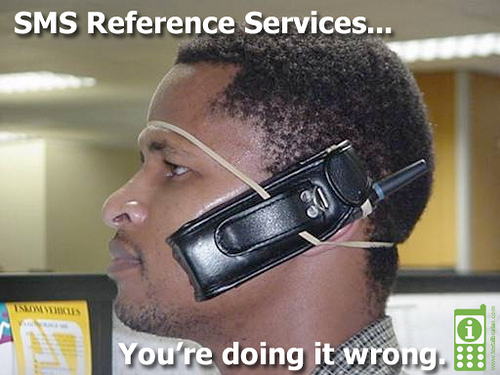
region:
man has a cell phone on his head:
[81, 8, 453, 368]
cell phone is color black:
[163, 128, 433, 318]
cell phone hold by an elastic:
[131, 105, 433, 305]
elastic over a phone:
[228, 162, 338, 267]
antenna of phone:
[376, 148, 436, 202]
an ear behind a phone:
[303, 208, 365, 265]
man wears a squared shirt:
[88, 8, 450, 373]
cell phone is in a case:
[162, 126, 437, 310]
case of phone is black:
[161, 135, 381, 312]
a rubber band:
[213, 149, 227, 169]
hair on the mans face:
[125, 308, 163, 329]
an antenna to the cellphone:
[380, 160, 430, 189]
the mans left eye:
[163, 160, 193, 177]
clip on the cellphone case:
[210, 213, 266, 257]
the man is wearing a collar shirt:
[361, 337, 391, 344]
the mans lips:
[102, 241, 136, 275]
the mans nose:
[104, 193, 151, 223]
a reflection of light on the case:
[192, 243, 222, 276]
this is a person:
[80, 6, 461, 342]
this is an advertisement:
[10, 12, 460, 362]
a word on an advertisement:
[13, 8, 83, 43]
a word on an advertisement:
[78, 0, 235, 65]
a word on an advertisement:
[240, 10, 400, 40]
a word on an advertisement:
[118, 328, 213, 373]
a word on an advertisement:
[310, 320, 335, 366]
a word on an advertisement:
[335, 340, 436, 373]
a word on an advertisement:
[166, 329, 216, 371]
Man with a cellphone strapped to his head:
[100, 19, 437, 374]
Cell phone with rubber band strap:
[142, 110, 399, 302]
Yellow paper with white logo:
[5, 290, 93, 374]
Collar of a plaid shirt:
[295, 313, 407, 373]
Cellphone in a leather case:
[168, 137, 427, 299]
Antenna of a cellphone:
[369, 159, 429, 206]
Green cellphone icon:
[450, 300, 487, 371]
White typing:
[8, 7, 398, 41]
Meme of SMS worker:
[2, 1, 499, 373]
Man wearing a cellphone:
[100, 14, 434, 374]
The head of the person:
[89, 11, 473, 360]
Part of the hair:
[308, 71, 350, 124]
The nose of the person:
[99, 148, 166, 231]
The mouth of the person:
[103, 233, 150, 285]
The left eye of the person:
[159, 155, 197, 180]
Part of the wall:
[56, 173, 84, 224]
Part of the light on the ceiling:
[2, 75, 54, 87]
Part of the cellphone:
[195, 228, 217, 265]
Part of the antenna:
[380, 164, 415, 196]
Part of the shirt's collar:
[374, 330, 390, 346]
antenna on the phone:
[385, 129, 430, 211]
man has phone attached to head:
[83, 25, 454, 345]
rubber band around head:
[126, 83, 419, 302]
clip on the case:
[205, 178, 328, 263]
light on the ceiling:
[2, 50, 92, 111]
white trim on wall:
[445, 73, 491, 278]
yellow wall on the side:
[431, 65, 491, 277]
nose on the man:
[96, 151, 156, 230]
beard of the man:
[103, 283, 211, 345]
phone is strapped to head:
[172, 142, 430, 296]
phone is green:
[449, 300, 486, 368]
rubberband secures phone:
[144, 120, 397, 252]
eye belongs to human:
[164, 157, 192, 178]